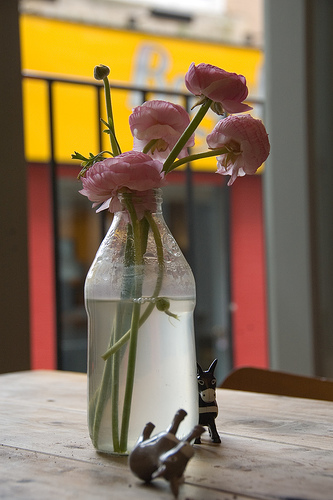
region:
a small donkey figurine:
[131, 405, 205, 493]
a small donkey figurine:
[193, 359, 220, 444]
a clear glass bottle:
[80, 189, 198, 454]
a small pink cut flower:
[78, 150, 163, 214]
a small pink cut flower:
[129, 99, 194, 160]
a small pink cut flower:
[183, 60, 254, 115]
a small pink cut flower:
[208, 114, 269, 184]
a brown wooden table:
[1, 367, 331, 498]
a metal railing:
[21, 73, 270, 375]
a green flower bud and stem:
[92, 62, 118, 151]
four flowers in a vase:
[96, 54, 271, 478]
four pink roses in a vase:
[73, 60, 268, 455]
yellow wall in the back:
[0, 11, 277, 151]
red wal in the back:
[19, 157, 275, 379]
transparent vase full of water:
[80, 199, 199, 457]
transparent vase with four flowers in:
[86, 191, 198, 459]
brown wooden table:
[1, 371, 329, 486]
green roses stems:
[91, 219, 143, 452]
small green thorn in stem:
[157, 295, 173, 330]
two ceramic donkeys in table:
[124, 365, 228, 488]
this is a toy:
[121, 394, 203, 495]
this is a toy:
[191, 357, 243, 462]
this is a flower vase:
[40, 44, 282, 452]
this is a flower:
[71, 145, 168, 261]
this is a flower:
[123, 79, 198, 159]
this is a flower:
[73, 57, 125, 158]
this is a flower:
[151, 55, 251, 164]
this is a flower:
[166, 113, 272, 189]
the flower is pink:
[168, 113, 290, 202]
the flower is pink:
[82, 148, 172, 233]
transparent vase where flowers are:
[86, 193, 203, 455]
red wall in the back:
[27, 157, 266, 372]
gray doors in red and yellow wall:
[50, 178, 228, 383]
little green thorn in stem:
[155, 290, 177, 328]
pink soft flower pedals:
[76, 150, 172, 215]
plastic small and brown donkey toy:
[127, 408, 206, 498]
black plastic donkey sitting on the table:
[192, 353, 239, 445]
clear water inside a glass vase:
[82, 295, 212, 456]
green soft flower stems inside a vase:
[76, 211, 223, 455]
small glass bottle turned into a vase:
[73, 186, 225, 458]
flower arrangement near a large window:
[25, 58, 320, 459]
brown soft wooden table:
[1, 364, 330, 498]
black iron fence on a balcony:
[18, 66, 284, 396]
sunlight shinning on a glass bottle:
[58, 206, 161, 298]